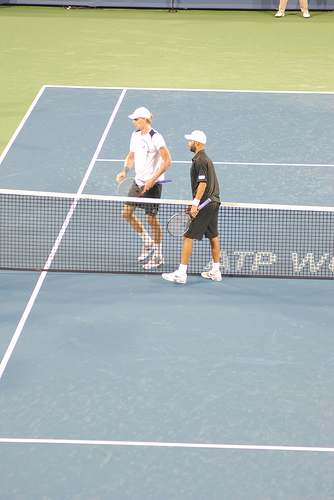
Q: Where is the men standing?
A: On the court.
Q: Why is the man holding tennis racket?
A: To play tennis.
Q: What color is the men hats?
A: Their white.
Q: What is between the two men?
A: A net.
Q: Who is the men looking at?
A: The ball.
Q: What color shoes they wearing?
A: All white.